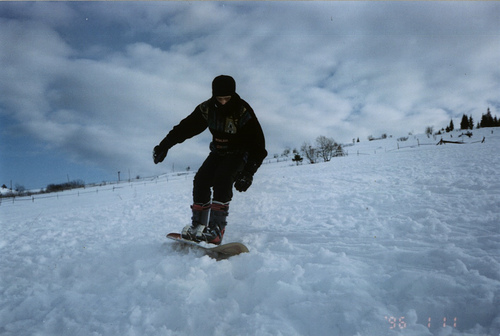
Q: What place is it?
A: It is a place.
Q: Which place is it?
A: It is a place.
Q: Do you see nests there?
A: No, there are no nests.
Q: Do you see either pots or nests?
A: No, there are no nests or pots.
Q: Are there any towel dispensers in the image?
A: No, there are no towel dispensers.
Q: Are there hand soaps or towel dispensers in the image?
A: No, there are no towel dispensers or hand soaps.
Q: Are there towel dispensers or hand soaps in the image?
A: No, there are no towel dispensers or hand soaps.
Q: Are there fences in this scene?
A: Yes, there is a fence.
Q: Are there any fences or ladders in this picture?
A: Yes, there is a fence.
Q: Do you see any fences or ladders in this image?
A: Yes, there is a fence.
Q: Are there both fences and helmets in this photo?
A: No, there is a fence but no helmets.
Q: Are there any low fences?
A: Yes, there is a low fence.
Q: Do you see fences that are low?
A: Yes, there is a fence that is low.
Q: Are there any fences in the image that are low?
A: Yes, there is a fence that is low.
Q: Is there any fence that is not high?
A: Yes, there is a low fence.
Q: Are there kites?
A: No, there are no kites.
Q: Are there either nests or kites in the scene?
A: No, there are no kites or nests.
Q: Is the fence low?
A: Yes, the fence is low.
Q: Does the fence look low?
A: Yes, the fence is low.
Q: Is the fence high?
A: No, the fence is low.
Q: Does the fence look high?
A: No, the fence is low.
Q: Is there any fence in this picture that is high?
A: No, there is a fence but it is low.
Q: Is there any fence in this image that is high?
A: No, there is a fence but it is low.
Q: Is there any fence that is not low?
A: No, there is a fence but it is low.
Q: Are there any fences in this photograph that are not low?
A: No, there is a fence but it is low.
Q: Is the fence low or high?
A: The fence is low.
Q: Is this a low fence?
A: Yes, this is a low fence.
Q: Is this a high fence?
A: No, this is a low fence.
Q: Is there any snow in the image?
A: Yes, there is snow.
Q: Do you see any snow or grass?
A: Yes, there is snow.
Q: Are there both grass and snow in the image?
A: No, there is snow but no grass.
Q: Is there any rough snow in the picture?
A: Yes, there is rough snow.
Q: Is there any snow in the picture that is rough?
A: Yes, there is snow that is rough.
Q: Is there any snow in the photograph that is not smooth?
A: Yes, there is rough snow.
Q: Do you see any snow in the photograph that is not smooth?
A: Yes, there is rough snow.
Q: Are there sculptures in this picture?
A: No, there are no sculptures.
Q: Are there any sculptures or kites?
A: No, there are no sculptures or kites.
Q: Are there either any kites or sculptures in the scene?
A: No, there are no sculptures or kites.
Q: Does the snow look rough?
A: Yes, the snow is rough.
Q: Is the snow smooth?
A: No, the snow is rough.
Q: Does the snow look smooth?
A: No, the snow is rough.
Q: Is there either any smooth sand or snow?
A: No, there is snow but it is rough.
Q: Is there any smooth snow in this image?
A: No, there is snow but it is rough.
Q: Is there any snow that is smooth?
A: No, there is snow but it is rough.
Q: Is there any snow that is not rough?
A: No, there is snow but it is rough.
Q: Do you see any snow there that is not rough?
A: No, there is snow but it is rough.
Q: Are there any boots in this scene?
A: Yes, there are boots.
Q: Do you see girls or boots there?
A: Yes, there are boots.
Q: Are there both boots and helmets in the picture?
A: No, there are boots but no helmets.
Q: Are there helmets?
A: No, there are no helmets.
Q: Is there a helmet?
A: No, there are no helmets.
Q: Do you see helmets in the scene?
A: No, there are no helmets.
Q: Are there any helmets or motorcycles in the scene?
A: No, there are no helmets or motorcycles.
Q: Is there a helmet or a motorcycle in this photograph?
A: No, there are no helmets or motorcycles.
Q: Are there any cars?
A: No, there are no cars.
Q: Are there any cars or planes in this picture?
A: No, there are no cars or planes.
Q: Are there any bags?
A: No, there are no bags.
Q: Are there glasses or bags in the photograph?
A: No, there are no bags or glasses.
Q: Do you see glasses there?
A: No, there are no glasses.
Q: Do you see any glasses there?
A: No, there are no glasses.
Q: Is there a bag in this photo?
A: No, there are no bags.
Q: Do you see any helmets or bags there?
A: No, there are no bags or helmets.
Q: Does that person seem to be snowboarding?
A: Yes, the person is snowboarding.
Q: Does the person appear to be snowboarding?
A: Yes, the person is snowboarding.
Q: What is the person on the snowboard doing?
A: The person is snowboarding.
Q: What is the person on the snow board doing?
A: The person is snowboarding.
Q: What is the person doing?
A: The person is snowboarding.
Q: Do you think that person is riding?
A: No, the person is snowboarding.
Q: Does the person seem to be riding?
A: No, the person is snowboarding.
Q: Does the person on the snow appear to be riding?
A: No, the person is snowboarding.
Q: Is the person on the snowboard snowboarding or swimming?
A: The person is snowboarding.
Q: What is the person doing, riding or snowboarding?
A: The person is snowboarding.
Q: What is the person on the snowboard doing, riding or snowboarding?
A: The person is snowboarding.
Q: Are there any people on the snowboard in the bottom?
A: Yes, there is a person on the snowboard.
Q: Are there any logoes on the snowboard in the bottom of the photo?
A: No, there is a person on the snowboard.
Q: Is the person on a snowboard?
A: Yes, the person is on a snowboard.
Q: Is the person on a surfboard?
A: No, the person is on a snowboard.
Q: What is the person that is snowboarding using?
A: The person is using a snowboard.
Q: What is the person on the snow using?
A: The person is using a snowboard.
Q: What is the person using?
A: The person is using a snowboard.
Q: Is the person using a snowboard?
A: Yes, the person is using a snowboard.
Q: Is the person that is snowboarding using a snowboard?
A: Yes, the person is using a snowboard.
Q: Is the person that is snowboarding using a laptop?
A: No, the person is using a snowboard.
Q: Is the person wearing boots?
A: Yes, the person is wearing boots.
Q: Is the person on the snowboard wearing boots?
A: Yes, the person is wearing boots.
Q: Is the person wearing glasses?
A: No, the person is wearing boots.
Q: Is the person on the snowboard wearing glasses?
A: No, the person is wearing boots.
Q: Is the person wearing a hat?
A: Yes, the person is wearing a hat.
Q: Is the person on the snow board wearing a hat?
A: Yes, the person is wearing a hat.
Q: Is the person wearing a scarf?
A: No, the person is wearing a hat.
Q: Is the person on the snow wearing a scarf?
A: No, the person is wearing a hat.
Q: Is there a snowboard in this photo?
A: Yes, there is a snowboard.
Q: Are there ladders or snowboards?
A: Yes, there is a snowboard.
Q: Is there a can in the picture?
A: No, there are no cans.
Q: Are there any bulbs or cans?
A: No, there are no cans or bulbs.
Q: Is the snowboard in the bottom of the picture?
A: Yes, the snowboard is in the bottom of the image.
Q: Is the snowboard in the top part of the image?
A: No, the snowboard is in the bottom of the image.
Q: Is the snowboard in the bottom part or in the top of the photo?
A: The snowboard is in the bottom of the image.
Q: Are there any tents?
A: No, there are no tents.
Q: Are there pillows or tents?
A: No, there are no tents or pillows.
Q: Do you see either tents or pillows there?
A: No, there are no tents or pillows.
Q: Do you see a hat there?
A: Yes, there is a hat.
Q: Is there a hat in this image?
A: Yes, there is a hat.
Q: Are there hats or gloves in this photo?
A: Yes, there is a hat.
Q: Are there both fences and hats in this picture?
A: Yes, there are both a hat and a fence.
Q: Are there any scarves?
A: No, there are no scarves.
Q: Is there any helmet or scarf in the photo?
A: No, there are no scarves or helmets.